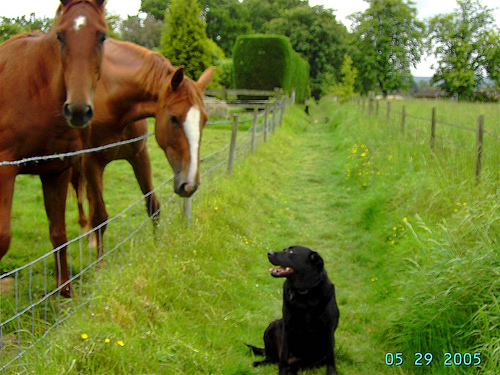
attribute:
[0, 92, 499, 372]
grass — long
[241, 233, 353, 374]
dog — black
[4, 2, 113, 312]
horse — brown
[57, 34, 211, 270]
horse — brown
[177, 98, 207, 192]
spot — white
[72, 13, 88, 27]
spot — white, small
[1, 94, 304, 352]
fence — wire